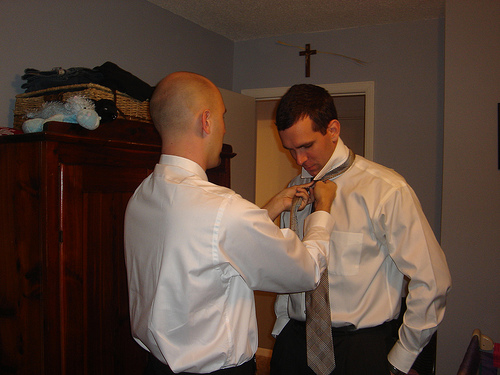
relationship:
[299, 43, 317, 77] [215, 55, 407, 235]
cross above doorway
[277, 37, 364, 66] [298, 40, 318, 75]
palm frond behind cross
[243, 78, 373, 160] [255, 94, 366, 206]
frame around doorway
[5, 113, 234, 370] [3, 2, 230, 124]
armoire against wall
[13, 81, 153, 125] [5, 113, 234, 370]
basket on top armoire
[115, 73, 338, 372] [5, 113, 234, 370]
man standing in front armoire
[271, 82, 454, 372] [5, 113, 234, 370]
man standing in front armoire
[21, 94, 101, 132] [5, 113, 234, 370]
stuffed animal on top armoire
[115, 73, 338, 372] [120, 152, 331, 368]
man wearing dress shirt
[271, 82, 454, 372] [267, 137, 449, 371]
man wearing dress shirt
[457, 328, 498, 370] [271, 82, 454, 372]
playpen right man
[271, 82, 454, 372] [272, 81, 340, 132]
man with hair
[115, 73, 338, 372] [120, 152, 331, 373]
man wearing dress shirt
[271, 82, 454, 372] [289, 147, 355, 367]
man wearing tie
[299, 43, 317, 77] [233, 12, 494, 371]
cross on wall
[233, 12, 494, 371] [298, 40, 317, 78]
wall with cross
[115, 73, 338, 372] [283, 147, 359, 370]
man tying necktie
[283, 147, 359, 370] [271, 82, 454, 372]
necktie of man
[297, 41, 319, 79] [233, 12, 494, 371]
cross on top wall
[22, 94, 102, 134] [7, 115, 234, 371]
stuffed animal on shelf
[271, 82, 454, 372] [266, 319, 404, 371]
man wearing pants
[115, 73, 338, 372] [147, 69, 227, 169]
man with head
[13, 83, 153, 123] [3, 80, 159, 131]
basket on shelf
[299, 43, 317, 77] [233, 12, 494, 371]
cross nailed to wall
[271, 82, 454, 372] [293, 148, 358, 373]
man wearing necktie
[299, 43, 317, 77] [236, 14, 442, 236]
cross on wall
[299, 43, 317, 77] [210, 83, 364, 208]
cross over door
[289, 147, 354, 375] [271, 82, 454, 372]
necktie on man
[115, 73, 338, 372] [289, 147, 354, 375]
man tying necktie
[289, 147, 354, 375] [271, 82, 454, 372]
necktie for man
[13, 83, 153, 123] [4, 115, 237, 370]
basket on armoir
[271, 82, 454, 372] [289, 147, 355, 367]
man looking at tie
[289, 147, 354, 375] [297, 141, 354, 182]
necktie around neck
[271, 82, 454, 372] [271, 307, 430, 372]
man wearing pants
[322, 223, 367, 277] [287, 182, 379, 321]
pocket on chest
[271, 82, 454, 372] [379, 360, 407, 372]
man has hand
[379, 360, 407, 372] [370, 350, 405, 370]
hand in pocket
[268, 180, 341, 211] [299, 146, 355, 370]
hands tying tie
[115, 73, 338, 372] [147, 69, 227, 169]
man has head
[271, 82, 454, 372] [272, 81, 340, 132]
man has hair